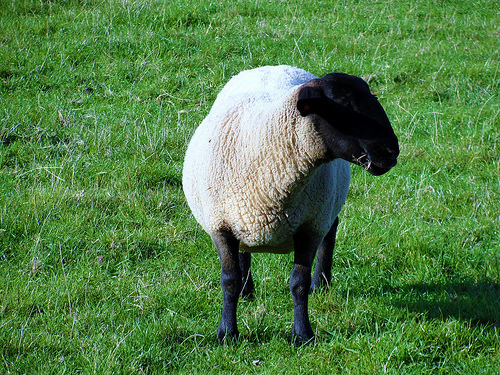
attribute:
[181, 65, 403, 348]
sheep — looking, standing, white, still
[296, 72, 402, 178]
head — black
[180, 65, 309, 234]
body — white, tan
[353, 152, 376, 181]
grass — growing, lush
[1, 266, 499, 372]
grass — green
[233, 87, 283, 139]
hair — shorn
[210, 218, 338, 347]
legs — black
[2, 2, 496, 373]
field — grassy, green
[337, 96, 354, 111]
right eye — black